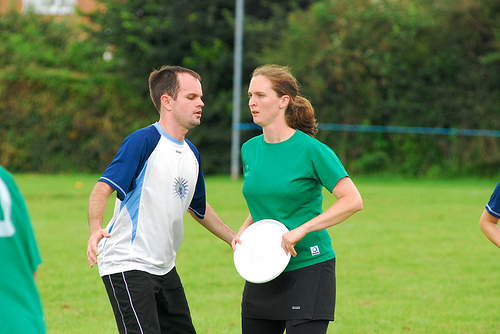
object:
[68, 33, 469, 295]
field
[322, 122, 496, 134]
pole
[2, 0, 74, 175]
trees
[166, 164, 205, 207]
image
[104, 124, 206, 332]
attire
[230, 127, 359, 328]
attire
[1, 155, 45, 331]
attire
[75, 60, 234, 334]
man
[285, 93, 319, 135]
pony tail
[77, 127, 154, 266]
arms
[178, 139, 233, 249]
arms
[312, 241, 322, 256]
tag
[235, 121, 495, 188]
net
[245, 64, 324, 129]
hair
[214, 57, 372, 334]
people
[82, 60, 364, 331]
couple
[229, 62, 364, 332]
lady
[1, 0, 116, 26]
building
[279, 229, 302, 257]
hands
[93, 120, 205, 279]
shirt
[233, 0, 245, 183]
pole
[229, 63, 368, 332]
she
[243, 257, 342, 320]
attire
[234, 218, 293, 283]
frisbee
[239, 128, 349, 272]
shirt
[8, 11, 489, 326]
park